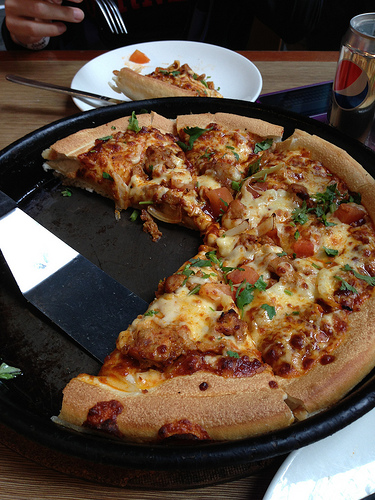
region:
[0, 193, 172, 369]
long metal spatula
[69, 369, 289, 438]
toasted brown pizza crust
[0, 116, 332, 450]
black pan under pizza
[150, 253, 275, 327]
green basil on pizza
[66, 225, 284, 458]
one slice of pizza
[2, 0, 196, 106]
a person holding a fork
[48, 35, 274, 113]
food on a white plate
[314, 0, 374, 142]
a silver can of pepsi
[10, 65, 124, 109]
a knife on the plate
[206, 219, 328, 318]
cheese and tomatoes on pizza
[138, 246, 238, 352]
pizza on a black tray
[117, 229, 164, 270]
black tray beneath pizza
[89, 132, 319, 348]
pizza with slices taken out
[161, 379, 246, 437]
brown crust of pizza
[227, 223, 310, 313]
toppings on the pizza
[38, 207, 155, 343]
silver spatula next to pizza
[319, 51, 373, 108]
pepsi logo on drink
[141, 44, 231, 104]
piece of pizza on white plate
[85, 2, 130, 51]
silver fork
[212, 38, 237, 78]
white plate under pizza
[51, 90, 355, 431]
This is cooked pizza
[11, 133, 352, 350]
The pizza is cut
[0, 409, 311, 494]
The pizza is on the table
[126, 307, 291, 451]
The cheese is brown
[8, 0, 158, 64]
The person has a fork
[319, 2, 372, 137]
This is a pepsi logo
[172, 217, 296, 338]
The pizza has tomatoes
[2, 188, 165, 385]
The spatula is silver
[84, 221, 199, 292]
The pan is black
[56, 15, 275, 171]
The plate is white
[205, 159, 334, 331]
this is a pizza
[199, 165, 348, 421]
the pizza is big in size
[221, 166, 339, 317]
the pizza is spicy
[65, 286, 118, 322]
this is a knife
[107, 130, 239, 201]
the pizza is yellow in color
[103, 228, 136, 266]
the pan is brown in color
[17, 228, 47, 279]
the knife is shiny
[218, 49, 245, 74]
the plate is white in color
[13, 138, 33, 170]
the pan is black in color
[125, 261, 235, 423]
the pizza is sliced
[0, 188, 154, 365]
a metal spatula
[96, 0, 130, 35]
the tines of a fork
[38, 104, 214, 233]
a slice of pizza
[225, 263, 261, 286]
a red slice of tomato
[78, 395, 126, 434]
a black spot on the crust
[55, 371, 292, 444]
a piece of brown crust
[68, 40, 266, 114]
a white plate on the table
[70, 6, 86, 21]
the fingernail of a person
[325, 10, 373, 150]
a can of soda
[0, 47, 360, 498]
a brown wooden table